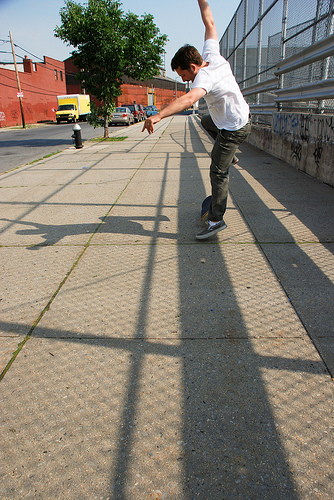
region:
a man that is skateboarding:
[113, 16, 332, 297]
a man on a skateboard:
[132, 66, 290, 285]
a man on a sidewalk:
[133, 26, 291, 248]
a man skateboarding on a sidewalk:
[126, 26, 305, 286]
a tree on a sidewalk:
[55, 3, 139, 153]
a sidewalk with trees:
[53, 7, 190, 170]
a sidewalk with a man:
[137, 13, 284, 222]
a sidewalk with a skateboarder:
[120, 26, 308, 330]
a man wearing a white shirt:
[151, 4, 285, 249]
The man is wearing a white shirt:
[139, 2, 251, 142]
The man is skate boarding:
[140, 5, 246, 235]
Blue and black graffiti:
[270, 106, 326, 155]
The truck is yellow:
[54, 95, 95, 125]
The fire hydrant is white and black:
[70, 123, 82, 148]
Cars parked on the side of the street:
[106, 101, 157, 126]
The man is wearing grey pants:
[138, 8, 248, 239]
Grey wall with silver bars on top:
[242, 32, 329, 173]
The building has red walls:
[3, 55, 185, 128]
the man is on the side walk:
[136, 3, 249, 247]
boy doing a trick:
[158, 173, 247, 255]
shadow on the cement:
[10, 203, 203, 255]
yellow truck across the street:
[45, 79, 94, 127]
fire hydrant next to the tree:
[64, 118, 88, 151]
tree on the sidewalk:
[54, 4, 136, 149]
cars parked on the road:
[106, 99, 163, 123]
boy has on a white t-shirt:
[166, 41, 257, 142]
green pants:
[199, 114, 242, 226]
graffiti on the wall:
[274, 104, 331, 182]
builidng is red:
[9, 46, 64, 118]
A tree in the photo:
[96, 24, 123, 86]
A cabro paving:
[147, 236, 223, 359]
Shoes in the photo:
[184, 195, 223, 247]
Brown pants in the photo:
[203, 134, 249, 192]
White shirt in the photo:
[207, 61, 240, 136]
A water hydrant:
[66, 117, 85, 147]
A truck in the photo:
[49, 85, 90, 125]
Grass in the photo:
[96, 133, 131, 147]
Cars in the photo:
[117, 101, 137, 125]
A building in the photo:
[35, 76, 54, 123]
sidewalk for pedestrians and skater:
[89, 152, 164, 466]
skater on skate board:
[130, 1, 259, 248]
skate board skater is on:
[198, 190, 213, 224]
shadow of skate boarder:
[7, 177, 194, 275]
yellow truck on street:
[49, 86, 92, 122]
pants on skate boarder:
[198, 115, 253, 217]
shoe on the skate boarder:
[193, 220, 230, 240]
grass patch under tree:
[89, 134, 127, 142]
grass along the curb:
[26, 151, 65, 164]